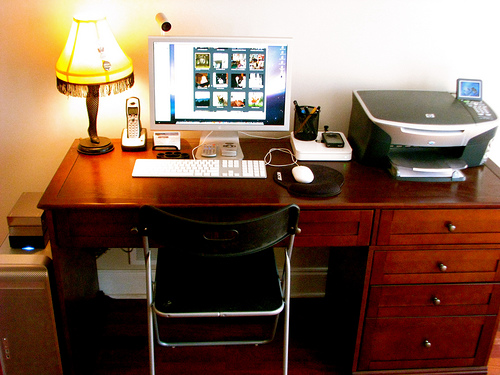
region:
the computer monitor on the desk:
[144, 30, 299, 134]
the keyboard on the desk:
[125, 151, 271, 185]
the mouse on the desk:
[286, 154, 314, 185]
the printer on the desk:
[347, 81, 497, 186]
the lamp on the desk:
[50, 6, 138, 159]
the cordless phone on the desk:
[117, 93, 146, 151]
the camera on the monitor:
[142, 10, 178, 37]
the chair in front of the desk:
[130, 200, 310, 373]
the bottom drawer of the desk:
[367, 310, 492, 370]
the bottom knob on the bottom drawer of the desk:
[415, 332, 438, 354]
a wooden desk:
[51, 119, 499, 373]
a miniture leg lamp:
[51, 4, 136, 159]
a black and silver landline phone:
[116, 92, 150, 151]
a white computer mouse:
[263, 144, 320, 194]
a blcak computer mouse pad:
[270, 155, 348, 203]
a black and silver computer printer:
[351, 80, 499, 193]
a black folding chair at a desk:
[112, 190, 322, 373]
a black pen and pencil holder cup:
[291, 98, 326, 153]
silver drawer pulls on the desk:
[419, 205, 464, 365]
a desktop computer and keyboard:
[136, 19, 298, 183]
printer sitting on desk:
[351, 82, 499, 179]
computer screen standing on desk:
[147, 35, 294, 134]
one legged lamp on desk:
[52, 13, 134, 155]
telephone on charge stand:
[121, 96, 146, 148]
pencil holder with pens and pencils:
[292, 98, 321, 140]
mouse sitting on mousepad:
[273, 163, 344, 198]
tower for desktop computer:
[2, 188, 63, 372]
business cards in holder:
[151, 128, 183, 153]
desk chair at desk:
[141, 203, 298, 374]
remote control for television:
[201, 139, 221, 158]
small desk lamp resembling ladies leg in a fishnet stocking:
[54, 10, 134, 155]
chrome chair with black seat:
[135, 200, 302, 372]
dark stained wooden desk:
[32, 135, 498, 372]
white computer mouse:
[291, 162, 312, 184]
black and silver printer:
[345, 77, 497, 186]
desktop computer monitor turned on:
[146, 33, 291, 138]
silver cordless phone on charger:
[117, 94, 147, 149]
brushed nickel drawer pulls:
[420, 220, 456, 350]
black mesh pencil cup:
[292, 103, 321, 145]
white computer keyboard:
[129, 152, 268, 184]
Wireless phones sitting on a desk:
[122, 96, 147, 148]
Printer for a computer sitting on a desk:
[347, 78, 494, 181]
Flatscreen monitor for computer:
[145, 35, 292, 132]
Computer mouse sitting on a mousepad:
[292, 164, 315, 184]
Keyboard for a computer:
[131, 158, 265, 178]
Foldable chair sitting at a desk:
[138, 204, 301, 374]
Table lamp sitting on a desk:
[53, 14, 135, 156]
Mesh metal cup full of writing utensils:
[291, 98, 320, 140]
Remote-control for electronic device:
[198, 142, 217, 155]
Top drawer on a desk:
[375, 207, 497, 242]